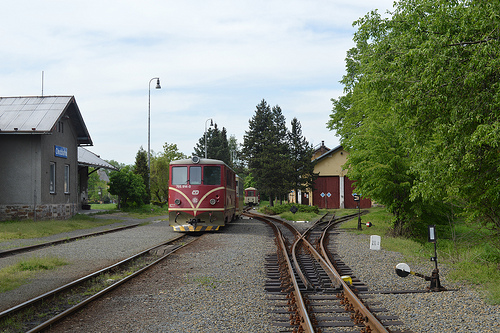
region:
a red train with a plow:
[163, 146, 239, 251]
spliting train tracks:
[248, 206, 373, 267]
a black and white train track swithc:
[385, 216, 468, 321]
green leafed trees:
[327, 21, 499, 230]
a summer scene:
[34, 91, 482, 293]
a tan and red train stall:
[303, 131, 408, 230]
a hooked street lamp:
[137, 59, 171, 188]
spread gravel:
[220, 244, 263, 331]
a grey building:
[7, 79, 118, 214]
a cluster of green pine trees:
[207, 116, 314, 196]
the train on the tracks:
[142, 151, 247, 237]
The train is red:
[158, 155, 250, 225]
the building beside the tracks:
[3, 89, 105, 220]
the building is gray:
[7, 85, 92, 220]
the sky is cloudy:
[157, 23, 296, 93]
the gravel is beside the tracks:
[157, 247, 255, 331]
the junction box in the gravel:
[359, 226, 474, 310]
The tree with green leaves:
[327, 5, 494, 222]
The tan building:
[299, 138, 389, 223]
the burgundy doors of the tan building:
[300, 161, 380, 218]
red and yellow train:
[169, 158, 229, 238]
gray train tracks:
[94, 233, 189, 295]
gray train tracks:
[267, 223, 352, 319]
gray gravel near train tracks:
[201, 239, 238, 331]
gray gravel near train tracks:
[414, 299, 461, 320]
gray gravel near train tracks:
[70, 241, 132, 257]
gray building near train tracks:
[11, 99, 87, 214]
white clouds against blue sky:
[47, 17, 331, 63]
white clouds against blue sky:
[172, 43, 229, 121]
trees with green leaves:
[359, 36, 471, 188]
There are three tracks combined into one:
[251, 189, 391, 326]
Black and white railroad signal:
[391, 222, 456, 298]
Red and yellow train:
[158, 141, 245, 237]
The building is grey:
[13, 87, 110, 242]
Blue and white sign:
[48, 137, 74, 159]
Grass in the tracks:
[41, 239, 190, 323]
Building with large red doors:
[290, 122, 392, 222]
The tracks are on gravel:
[61, 234, 448, 324]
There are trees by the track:
[350, 25, 490, 232]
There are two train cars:
[168, 146, 263, 246]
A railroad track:
[111, 244, 168, 265]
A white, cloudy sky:
[136, 15, 327, 80]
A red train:
[158, 155, 242, 236]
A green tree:
[386, 27, 486, 173]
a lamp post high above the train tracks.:
[101, 71, 174, 102]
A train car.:
[241, 182, 266, 213]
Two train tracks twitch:
[285, 221, 344, 272]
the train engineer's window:
[178, 167, 215, 192]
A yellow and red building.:
[312, 152, 353, 204]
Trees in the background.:
[108, 157, 156, 201]